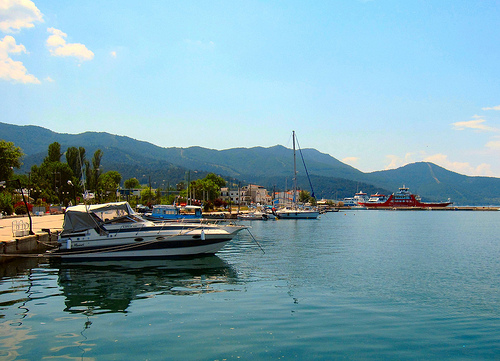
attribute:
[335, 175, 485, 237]
ship — long, red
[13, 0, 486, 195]
sky — cloudy, blue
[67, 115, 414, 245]
hills — long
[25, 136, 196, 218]
trees — lush, green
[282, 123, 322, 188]
mast — tall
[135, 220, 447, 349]
water — blue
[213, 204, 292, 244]
cable — anchor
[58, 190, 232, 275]
boat — striped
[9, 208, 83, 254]
dock — floating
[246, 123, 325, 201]
sailboat — tall-masted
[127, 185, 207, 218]
cabin — white, blue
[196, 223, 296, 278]
chain — anchor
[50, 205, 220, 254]
boat — tied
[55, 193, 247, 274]
boats — large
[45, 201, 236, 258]
boats — parked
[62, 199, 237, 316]
boats — floating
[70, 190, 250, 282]
boats — waiting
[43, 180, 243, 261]
boats — close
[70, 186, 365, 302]
boats — tied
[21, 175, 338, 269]
boats — used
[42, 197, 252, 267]
boat — docked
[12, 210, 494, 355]
water — calm, large, wide open, blue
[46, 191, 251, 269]
boat — docked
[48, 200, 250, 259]
boat — docked, small, wooden, white, white and black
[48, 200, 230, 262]
boat — docked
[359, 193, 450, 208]
boat — large, red, metal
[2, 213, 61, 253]
dock — large, wide, wooden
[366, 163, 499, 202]
mountain — large, wide, tall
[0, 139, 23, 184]
tree — tall, large, green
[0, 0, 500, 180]
sky — wide open, large, cloudy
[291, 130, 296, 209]
mast — tall, brown, wooden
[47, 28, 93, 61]
cloud — small, fluffy, white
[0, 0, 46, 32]
cloud — large, wide, fluffy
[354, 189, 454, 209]
boat — large, red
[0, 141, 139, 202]
trees — tall, green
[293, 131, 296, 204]
pole — tall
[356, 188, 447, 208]
ship — red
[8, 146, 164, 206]
trees — green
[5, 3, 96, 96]
clouds — fluffy